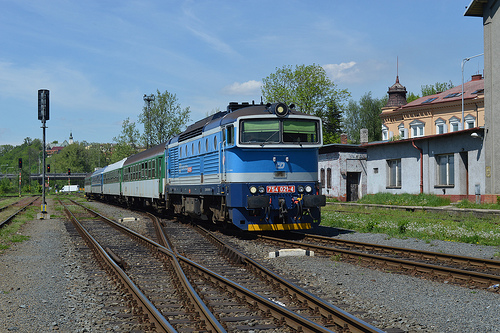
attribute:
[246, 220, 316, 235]
trim — yellow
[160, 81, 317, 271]
locomotive — primarily blue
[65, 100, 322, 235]
train — pictured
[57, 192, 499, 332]
tracks — criss-crossed, train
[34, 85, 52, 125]
signal — traffic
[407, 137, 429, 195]
gutter — red, rain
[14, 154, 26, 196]
stop light — pictured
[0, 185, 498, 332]
tracks — parallel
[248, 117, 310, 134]
shades — sun-blocker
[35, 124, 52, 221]
pole — metal 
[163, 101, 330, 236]
engine — white, blue, passenger, train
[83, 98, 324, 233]
train car — blue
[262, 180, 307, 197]
letters — white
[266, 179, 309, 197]
numbers — white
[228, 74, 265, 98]
clouds — small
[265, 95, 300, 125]
head light — round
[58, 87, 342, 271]
train — passenger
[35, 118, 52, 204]
pole — tall, thin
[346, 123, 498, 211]
building — grey, one-story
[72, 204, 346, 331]
tracks — double set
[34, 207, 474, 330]
tracks — train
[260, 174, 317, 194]
plate — red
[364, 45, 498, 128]
building — yellow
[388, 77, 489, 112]
roof — red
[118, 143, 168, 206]
train car — green, white, passenger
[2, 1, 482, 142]
sky — bright blue